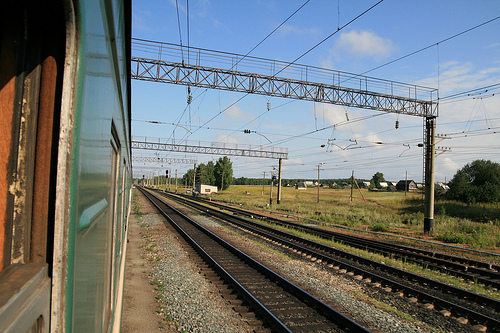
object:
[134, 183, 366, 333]
rail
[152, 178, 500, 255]
grass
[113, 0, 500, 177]
blue sky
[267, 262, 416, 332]
gray ballast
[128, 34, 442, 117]
scaffolding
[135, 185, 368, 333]
track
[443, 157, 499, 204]
green tree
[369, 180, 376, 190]
green tree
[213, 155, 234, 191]
green tree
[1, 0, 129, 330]
green train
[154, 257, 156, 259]
gravel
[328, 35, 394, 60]
cloud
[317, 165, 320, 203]
pole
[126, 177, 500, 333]
countryside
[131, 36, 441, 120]
bars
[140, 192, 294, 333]
steel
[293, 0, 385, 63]
power lines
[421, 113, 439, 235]
pole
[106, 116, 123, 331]
window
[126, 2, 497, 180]
cloud